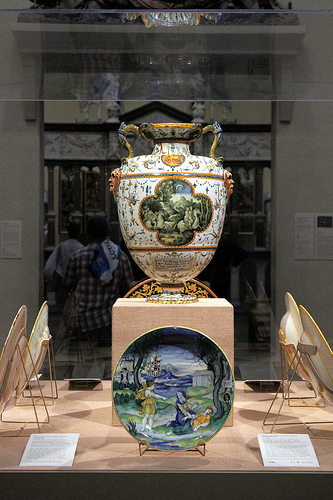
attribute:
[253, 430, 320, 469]
paper — white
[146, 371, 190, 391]
waters — turbulent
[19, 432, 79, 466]
paper — white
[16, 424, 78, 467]
placards — white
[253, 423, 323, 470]
placards — white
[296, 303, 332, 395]
rim plates — gold rimmed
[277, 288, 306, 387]
rim plates — gold rimmed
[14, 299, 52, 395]
rim plates — gold rimmed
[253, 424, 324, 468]
paper — white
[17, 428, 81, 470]
paper — white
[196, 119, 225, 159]
handle — gold, blue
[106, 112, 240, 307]
vase — ornate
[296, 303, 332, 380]
plate — gold rimmed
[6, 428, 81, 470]
paper — white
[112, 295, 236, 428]
block — concrete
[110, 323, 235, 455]
plate — displayed, gold rimmed